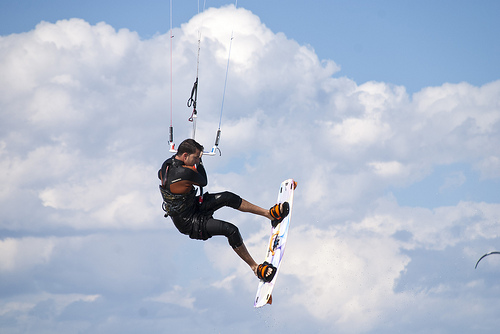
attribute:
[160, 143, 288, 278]
man — in air, surfing, skydiving, in black, standing, in sky, parasailing, in the water, in the air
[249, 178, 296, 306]
surfboard — white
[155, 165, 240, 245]
clothing — black, tight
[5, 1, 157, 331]
sky — cloudy, light, blue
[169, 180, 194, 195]
shirt — orange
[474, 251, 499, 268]
parachute — in background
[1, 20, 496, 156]
clouds — white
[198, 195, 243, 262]
pants — black